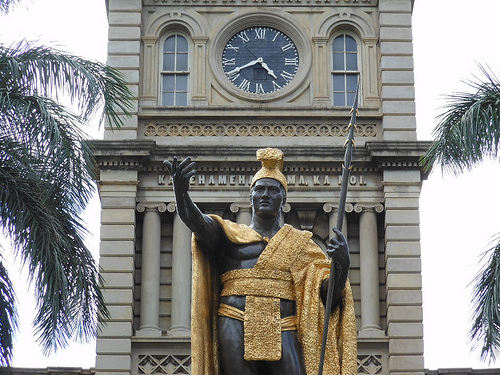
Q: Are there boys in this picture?
A: No, there are no boys.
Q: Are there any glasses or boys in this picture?
A: No, there are no boys or glasses.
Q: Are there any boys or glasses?
A: No, there are no boys or glasses.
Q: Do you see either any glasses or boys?
A: No, there are no boys or glasses.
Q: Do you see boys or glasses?
A: No, there are no boys or glasses.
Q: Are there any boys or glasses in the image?
A: No, there are no glasses or boys.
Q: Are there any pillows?
A: No, there are no pillows.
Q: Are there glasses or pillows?
A: No, there are no pillows or glasses.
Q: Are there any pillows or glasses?
A: No, there are no pillows or glasses.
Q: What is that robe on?
A: The robe is on the statue.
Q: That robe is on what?
A: The robe is on the statue.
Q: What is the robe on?
A: The robe is on the statue.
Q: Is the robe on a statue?
A: Yes, the robe is on a statue.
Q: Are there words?
A: Yes, there are words.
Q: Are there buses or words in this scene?
A: Yes, there are words.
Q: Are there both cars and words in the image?
A: No, there are words but no cars.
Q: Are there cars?
A: No, there are no cars.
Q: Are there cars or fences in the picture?
A: No, there are no cars or fences.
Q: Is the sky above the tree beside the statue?
A: Yes, the sky is above the tree.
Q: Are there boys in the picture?
A: No, there are no boys.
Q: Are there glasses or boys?
A: No, there are no boys or glasses.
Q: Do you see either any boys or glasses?
A: No, there are no boys or glasses.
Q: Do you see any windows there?
A: Yes, there is a window.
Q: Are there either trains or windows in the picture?
A: Yes, there is a window.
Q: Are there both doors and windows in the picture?
A: No, there is a window but no doors.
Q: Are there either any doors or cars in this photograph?
A: No, there are no cars or doors.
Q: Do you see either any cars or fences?
A: No, there are no cars or fences.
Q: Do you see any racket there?
A: No, there are no rackets.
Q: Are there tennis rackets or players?
A: No, there are no tennis rackets or players.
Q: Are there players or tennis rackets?
A: No, there are no tennis rackets or players.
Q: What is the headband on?
A: The headband is on the statue.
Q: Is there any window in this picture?
A: Yes, there is a window.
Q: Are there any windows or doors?
A: Yes, there is a window.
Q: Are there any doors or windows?
A: Yes, there is a window.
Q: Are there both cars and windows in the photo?
A: No, there is a window but no cars.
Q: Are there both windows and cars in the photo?
A: No, there is a window but no cars.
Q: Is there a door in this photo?
A: No, there are no doors.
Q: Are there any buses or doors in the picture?
A: No, there are no doors or buses.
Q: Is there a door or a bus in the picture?
A: No, there are no doors or buses.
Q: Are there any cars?
A: No, there are no cars.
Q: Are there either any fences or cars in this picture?
A: No, there are no cars or fences.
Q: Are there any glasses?
A: No, there are no glasses.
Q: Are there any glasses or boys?
A: No, there are no glasses or boys.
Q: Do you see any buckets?
A: No, there are no buckets.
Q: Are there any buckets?
A: No, there are no buckets.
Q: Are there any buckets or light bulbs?
A: No, there are no buckets or light bulbs.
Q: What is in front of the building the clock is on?
A: The statue is in front of the building.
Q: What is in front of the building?
A: The statue is in front of the building.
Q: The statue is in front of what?
A: The statue is in front of the building.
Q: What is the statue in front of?
A: The statue is in front of the building.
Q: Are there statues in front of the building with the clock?
A: Yes, there is a statue in front of the building.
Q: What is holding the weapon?
A: The statue is holding the weapon.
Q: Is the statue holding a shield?
A: No, the statue is holding a weapon.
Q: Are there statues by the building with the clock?
A: Yes, there is a statue by the building.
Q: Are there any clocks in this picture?
A: Yes, there is a clock.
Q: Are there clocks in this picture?
A: Yes, there is a clock.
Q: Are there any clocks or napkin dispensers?
A: Yes, there is a clock.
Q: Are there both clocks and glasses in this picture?
A: No, there is a clock but no glasses.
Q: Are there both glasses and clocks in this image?
A: No, there is a clock but no glasses.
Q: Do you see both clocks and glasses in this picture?
A: No, there is a clock but no glasses.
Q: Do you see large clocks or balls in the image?
A: Yes, there is a large clock.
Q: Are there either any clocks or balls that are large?
A: Yes, the clock is large.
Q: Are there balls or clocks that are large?
A: Yes, the clock is large.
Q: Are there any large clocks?
A: Yes, there is a large clock.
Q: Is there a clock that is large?
A: Yes, there is a clock that is large.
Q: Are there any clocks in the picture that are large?
A: Yes, there is a clock that is large.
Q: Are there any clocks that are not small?
A: Yes, there is a large clock.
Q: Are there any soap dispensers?
A: No, there are no soap dispensers.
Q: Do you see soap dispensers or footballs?
A: No, there are no soap dispensers or footballs.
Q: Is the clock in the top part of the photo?
A: Yes, the clock is in the top of the image.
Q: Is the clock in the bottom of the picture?
A: No, the clock is in the top of the image.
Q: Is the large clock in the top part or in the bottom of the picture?
A: The clock is in the top of the image.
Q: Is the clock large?
A: Yes, the clock is large.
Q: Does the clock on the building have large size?
A: Yes, the clock is large.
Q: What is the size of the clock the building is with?
A: The clock is large.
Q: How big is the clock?
A: The clock is large.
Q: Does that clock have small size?
A: No, the clock is large.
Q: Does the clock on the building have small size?
A: No, the clock is large.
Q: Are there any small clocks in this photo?
A: No, there is a clock but it is large.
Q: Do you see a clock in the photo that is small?
A: No, there is a clock but it is large.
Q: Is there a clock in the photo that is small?
A: No, there is a clock but it is large.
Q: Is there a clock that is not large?
A: No, there is a clock but it is large.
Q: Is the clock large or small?
A: The clock is large.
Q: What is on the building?
A: The clock is on the building.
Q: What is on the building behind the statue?
A: The clock is on the building.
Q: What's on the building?
A: The clock is on the building.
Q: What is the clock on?
A: The clock is on the building.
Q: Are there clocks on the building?
A: Yes, there is a clock on the building.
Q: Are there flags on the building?
A: No, there is a clock on the building.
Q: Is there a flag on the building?
A: No, there is a clock on the building.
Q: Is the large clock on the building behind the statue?
A: Yes, the clock is on the building.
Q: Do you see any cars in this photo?
A: No, there are no cars.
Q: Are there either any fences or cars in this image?
A: No, there are no cars or fences.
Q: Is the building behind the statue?
A: Yes, the building is behind the statue.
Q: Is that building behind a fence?
A: No, the building is behind the statue.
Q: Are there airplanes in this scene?
A: No, there are no airplanes.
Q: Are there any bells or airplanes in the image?
A: No, there are no airplanes or bells.